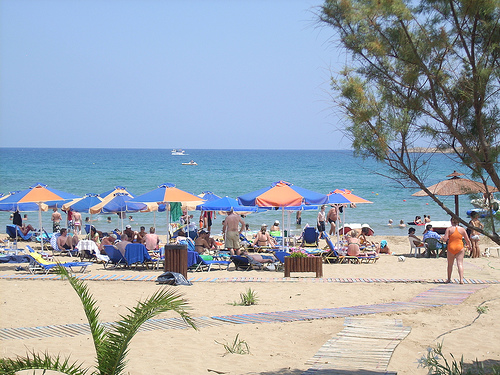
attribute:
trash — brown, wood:
[276, 258, 339, 284]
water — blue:
[217, 152, 282, 185]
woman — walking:
[426, 231, 479, 279]